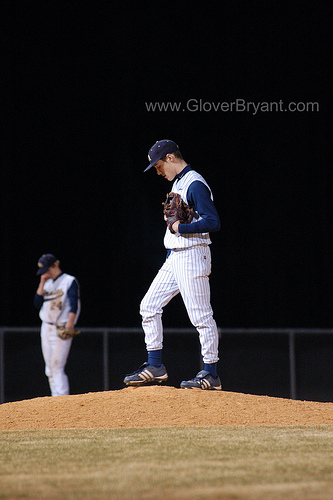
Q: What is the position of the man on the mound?
A: A pitcher.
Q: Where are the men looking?
A: They are looking down.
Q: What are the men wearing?
A: White and blue uniforms.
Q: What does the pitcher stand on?
A: A mound.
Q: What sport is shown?
A: Baseball.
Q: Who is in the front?
A: The pitcher.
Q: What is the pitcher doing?
A: Preparing to throw.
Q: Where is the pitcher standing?
A: On the mound.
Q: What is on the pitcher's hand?
A: A mitt.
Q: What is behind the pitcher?
A: A fence.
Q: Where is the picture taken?
A: Baseball diamond.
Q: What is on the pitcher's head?
A: A hat.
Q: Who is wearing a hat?
A: The baseball players.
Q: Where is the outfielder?
A: Behind the pitcher.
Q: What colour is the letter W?
A: White.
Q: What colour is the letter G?
A: White.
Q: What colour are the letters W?
A: White.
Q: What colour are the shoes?
A: Blue.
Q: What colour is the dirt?
A: Brown.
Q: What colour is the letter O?
A: White.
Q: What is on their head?
A: Cap.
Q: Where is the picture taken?
A: At the ballpark.